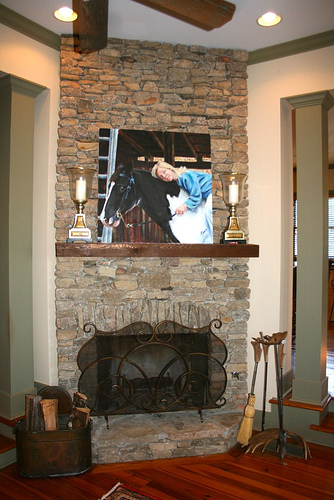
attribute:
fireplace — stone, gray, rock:
[55, 34, 260, 467]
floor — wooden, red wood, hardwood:
[1, 432, 330, 500]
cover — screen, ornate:
[75, 318, 229, 424]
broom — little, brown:
[237, 342, 260, 448]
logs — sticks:
[24, 393, 91, 431]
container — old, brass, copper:
[13, 415, 91, 478]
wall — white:
[247, 45, 333, 411]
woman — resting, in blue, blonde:
[151, 159, 216, 237]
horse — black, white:
[98, 157, 212, 245]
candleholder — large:
[221, 173, 246, 245]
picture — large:
[98, 128, 211, 246]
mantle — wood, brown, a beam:
[53, 242, 259, 258]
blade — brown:
[136, 1, 235, 32]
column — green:
[288, 92, 329, 414]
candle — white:
[229, 182, 241, 205]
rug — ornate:
[100, 484, 158, 500]